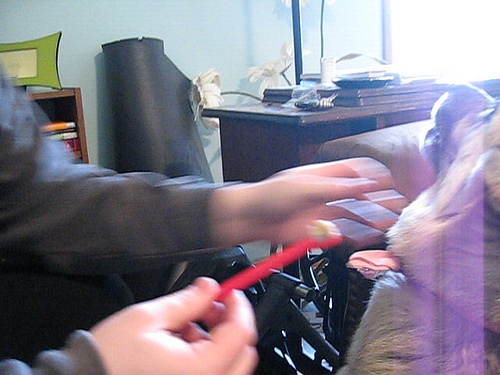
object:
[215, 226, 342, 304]
object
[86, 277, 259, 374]
hand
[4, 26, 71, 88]
picture frame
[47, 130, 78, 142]
books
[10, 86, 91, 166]
shelf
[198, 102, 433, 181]
desk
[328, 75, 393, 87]
dish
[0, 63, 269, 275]
arm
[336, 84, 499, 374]
dog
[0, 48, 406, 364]
man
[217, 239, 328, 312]
straw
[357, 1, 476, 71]
window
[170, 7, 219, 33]
walls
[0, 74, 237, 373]
shirt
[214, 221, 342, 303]
toothbrush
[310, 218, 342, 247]
bandana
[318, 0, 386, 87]
light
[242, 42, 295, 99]
flowers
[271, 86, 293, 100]
material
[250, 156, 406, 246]
hands